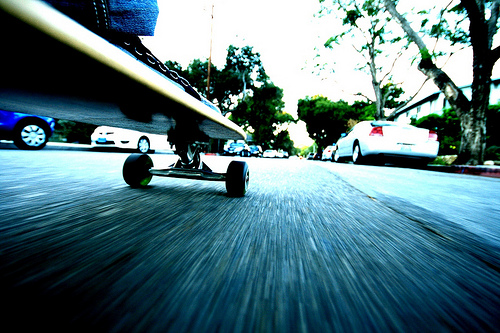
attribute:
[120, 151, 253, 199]
wheels — rolling, green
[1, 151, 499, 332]
street — gray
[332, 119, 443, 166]
sedan — silver, parked, white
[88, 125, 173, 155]
sedan — white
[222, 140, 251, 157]
sedan — black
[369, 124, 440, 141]
brakes — red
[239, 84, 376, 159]
trees — standing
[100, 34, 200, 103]
socks — black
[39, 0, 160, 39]
jeans — blue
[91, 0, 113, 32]
seam — white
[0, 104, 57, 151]
vehicle — blue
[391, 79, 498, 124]
house — white, big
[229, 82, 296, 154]
tree — green